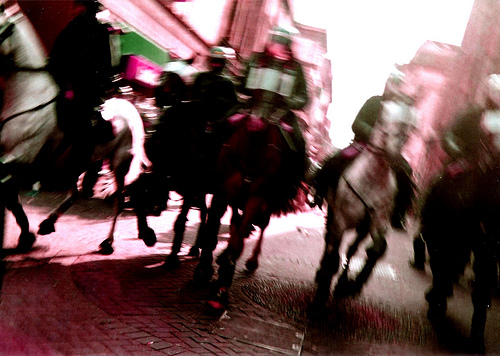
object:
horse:
[179, 95, 310, 319]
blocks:
[0, 189, 500, 356]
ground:
[0, 206, 489, 355]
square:
[213, 310, 304, 355]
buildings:
[381, 0, 500, 190]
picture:
[0, 0, 500, 355]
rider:
[45, 0, 137, 167]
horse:
[0, 0, 157, 255]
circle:
[69, 236, 204, 355]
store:
[68, 13, 179, 188]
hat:
[267, 24, 295, 48]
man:
[230, 19, 307, 134]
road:
[0, 206, 500, 355]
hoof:
[190, 266, 212, 286]